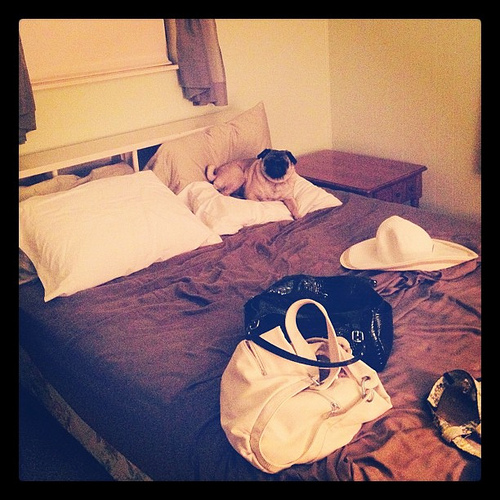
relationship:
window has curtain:
[20, 16, 176, 83] [164, 16, 229, 109]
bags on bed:
[220, 296, 393, 474] [20, 107, 481, 482]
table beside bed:
[294, 148, 426, 209] [20, 107, 481, 482]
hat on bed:
[339, 213, 481, 275] [20, 107, 481, 482]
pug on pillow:
[204, 148, 303, 220] [154, 102, 344, 239]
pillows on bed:
[23, 100, 344, 302] [20, 107, 481, 482]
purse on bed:
[243, 275, 396, 370] [20, 107, 481, 482]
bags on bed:
[220, 273, 393, 477] [20, 107, 481, 482]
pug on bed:
[204, 148, 303, 220] [20, 107, 481, 482]